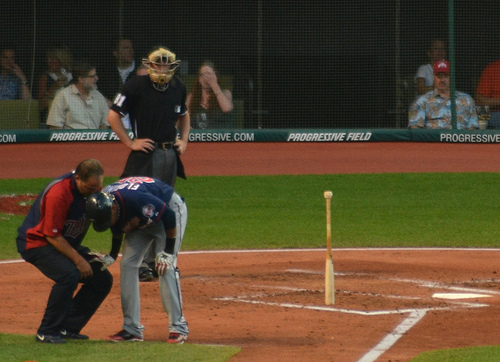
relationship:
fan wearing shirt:
[414, 50, 480, 138] [414, 90, 484, 135]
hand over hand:
[201, 68, 217, 83] [201, 68, 217, 83]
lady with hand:
[176, 62, 234, 129] [201, 68, 217, 83]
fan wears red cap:
[407, 61, 480, 130] [428, 53, 453, 76]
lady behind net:
[194, 55, 240, 127] [1, 0, 498, 131]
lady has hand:
[194, 55, 240, 127] [206, 74, 217, 86]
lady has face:
[194, 55, 240, 127] [195, 64, 217, 85]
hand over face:
[206, 74, 217, 86] [195, 64, 217, 85]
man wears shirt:
[19, 153, 116, 338] [22, 176, 87, 243]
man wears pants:
[19, 153, 116, 338] [19, 241, 105, 332]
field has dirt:
[2, 147, 496, 359] [175, 252, 492, 352]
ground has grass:
[443, 141, 468, 158] [177, 173, 495, 246]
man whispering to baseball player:
[16, 158, 114, 344] [89, 176, 188, 348]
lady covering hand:
[176, 62, 234, 129] [201, 68, 217, 83]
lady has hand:
[176, 62, 234, 129] [204, 73, 221, 85]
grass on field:
[214, 189, 316, 233] [1, 177, 497, 359]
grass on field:
[360, 183, 436, 233] [1, 177, 497, 359]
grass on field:
[5, 340, 183, 360] [1, 177, 497, 359]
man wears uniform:
[16, 158, 114, 344] [13, 168, 117, 345]